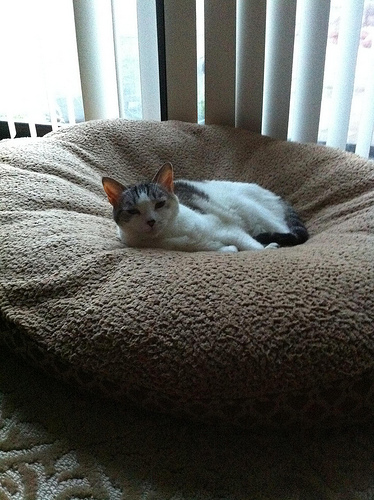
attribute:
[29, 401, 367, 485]
rug — tan, cream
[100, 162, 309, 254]
cat — black, white, large, striped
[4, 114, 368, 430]
bed — large, fuzzy, brown, cat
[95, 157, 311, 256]
cat — pointy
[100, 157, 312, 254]
tabby — grey, white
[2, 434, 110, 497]
design — fleur de lis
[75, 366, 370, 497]
shadow — dark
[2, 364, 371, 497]
carpet — beige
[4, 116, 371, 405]
pet pillow — brown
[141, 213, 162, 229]
nose — black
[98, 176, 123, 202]
ear — inner, pink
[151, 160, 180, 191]
ear — inner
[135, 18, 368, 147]
vertical blinds — white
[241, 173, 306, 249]
back end — white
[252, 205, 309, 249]
tail — gray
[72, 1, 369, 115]
blinds — white, vertical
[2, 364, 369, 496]
carpeting — tan, brown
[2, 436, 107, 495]
pattern — raised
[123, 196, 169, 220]
eyes — open